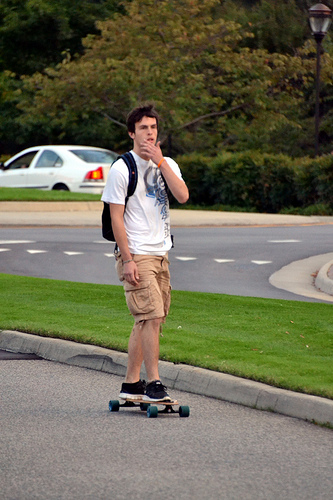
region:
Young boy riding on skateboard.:
[98, 101, 195, 421]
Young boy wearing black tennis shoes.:
[109, 379, 176, 402]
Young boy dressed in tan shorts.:
[112, 251, 176, 323]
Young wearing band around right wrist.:
[119, 257, 139, 270]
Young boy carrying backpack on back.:
[99, 150, 138, 243]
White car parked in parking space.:
[1, 143, 120, 200]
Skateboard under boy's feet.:
[101, 396, 191, 423]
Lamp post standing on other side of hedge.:
[297, 1, 330, 162]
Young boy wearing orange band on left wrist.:
[155, 156, 172, 169]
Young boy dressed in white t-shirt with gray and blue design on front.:
[98, 150, 186, 257]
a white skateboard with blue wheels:
[106, 393, 188, 416]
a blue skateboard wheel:
[143, 405, 158, 414]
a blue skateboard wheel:
[177, 404, 187, 412]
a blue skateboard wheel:
[107, 397, 114, 406]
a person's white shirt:
[101, 149, 180, 252]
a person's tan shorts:
[115, 254, 172, 317]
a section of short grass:
[0, 275, 330, 397]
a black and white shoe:
[141, 379, 170, 399]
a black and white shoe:
[116, 378, 145, 399]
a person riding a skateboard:
[100, 106, 191, 418]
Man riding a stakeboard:
[98, 368, 192, 414]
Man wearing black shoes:
[115, 370, 178, 411]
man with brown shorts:
[95, 250, 183, 330]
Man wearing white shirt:
[108, 156, 188, 257]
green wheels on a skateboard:
[141, 396, 200, 433]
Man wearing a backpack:
[77, 140, 162, 225]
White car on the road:
[20, 134, 124, 210]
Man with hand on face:
[133, 133, 182, 181]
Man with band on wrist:
[150, 157, 179, 179]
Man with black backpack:
[105, 157, 146, 205]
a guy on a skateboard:
[96, 101, 191, 420]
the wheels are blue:
[105, 396, 189, 417]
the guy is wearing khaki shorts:
[113, 249, 173, 323]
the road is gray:
[2, 329, 332, 495]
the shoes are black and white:
[119, 378, 171, 403]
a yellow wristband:
[153, 155, 167, 170]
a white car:
[1, 140, 123, 193]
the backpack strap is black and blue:
[117, 147, 142, 197]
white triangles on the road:
[0, 244, 274, 266]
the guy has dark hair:
[122, 98, 161, 147]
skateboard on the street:
[105, 394, 194, 418]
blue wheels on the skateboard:
[107, 398, 191, 419]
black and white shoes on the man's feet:
[118, 374, 174, 403]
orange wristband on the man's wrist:
[155, 154, 165, 167]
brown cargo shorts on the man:
[113, 244, 175, 327]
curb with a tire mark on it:
[0, 326, 332, 433]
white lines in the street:
[0, 235, 305, 268]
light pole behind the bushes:
[300, 0, 331, 148]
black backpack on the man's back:
[99, 150, 140, 242]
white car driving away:
[0, 141, 119, 195]